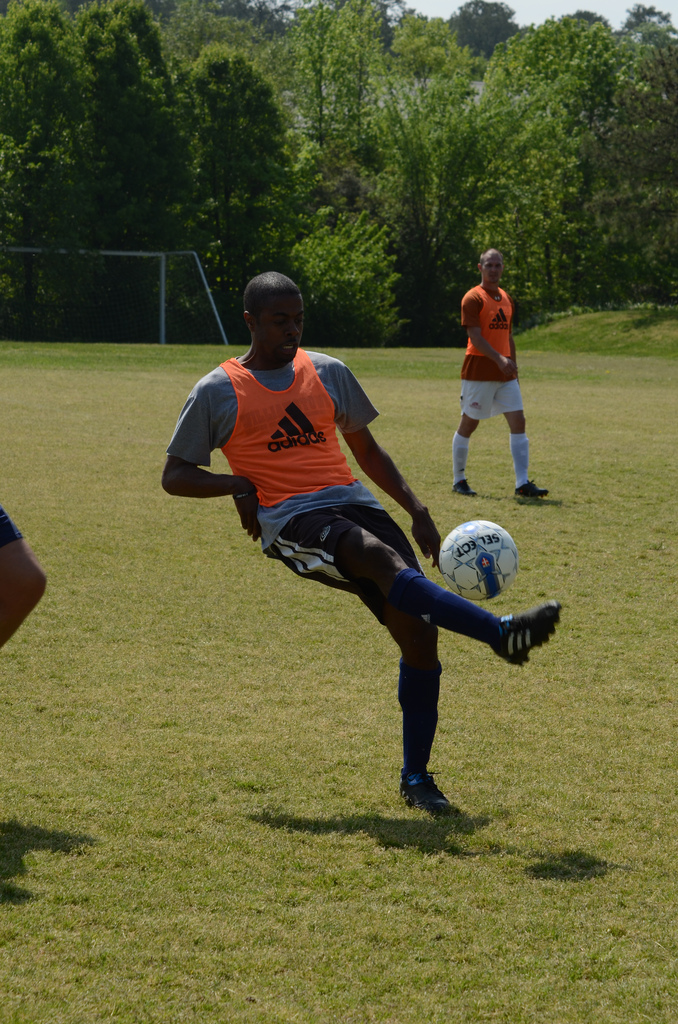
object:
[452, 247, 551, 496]
man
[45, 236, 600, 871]
field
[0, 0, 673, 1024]
picture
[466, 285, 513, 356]
vest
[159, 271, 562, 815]
man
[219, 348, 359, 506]
vest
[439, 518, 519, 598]
ball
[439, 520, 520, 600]
stripe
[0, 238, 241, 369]
goal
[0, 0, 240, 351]
tree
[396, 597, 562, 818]
shoes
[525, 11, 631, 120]
green tree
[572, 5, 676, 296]
green tree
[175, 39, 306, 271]
green tree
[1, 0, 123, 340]
green tree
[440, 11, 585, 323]
green tree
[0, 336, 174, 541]
field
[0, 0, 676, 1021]
soccer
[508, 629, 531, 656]
stripes